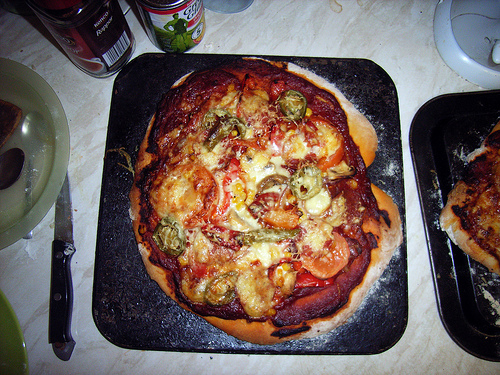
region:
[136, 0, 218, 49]
A can of vegetables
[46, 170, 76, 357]
A knife with the tip hidden under a plate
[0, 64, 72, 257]
A green plate with food on it, and a spoon underneath it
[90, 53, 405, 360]
A pizza on a platter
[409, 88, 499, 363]
Part of a platter of pizza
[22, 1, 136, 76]
A bottle of juice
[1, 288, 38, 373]
The edge of a green plate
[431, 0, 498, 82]
A white and grey object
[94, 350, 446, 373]
A white marble table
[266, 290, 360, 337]
Burnt sauce and crust of the pizza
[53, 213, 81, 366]
Knife to the left of the plate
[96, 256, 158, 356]
Bottom left corner of the black pate the pizza rests on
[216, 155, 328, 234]
Cheesy middle of the pizza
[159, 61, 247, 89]
Crispy crust at the top of the pizza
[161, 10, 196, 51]
Green giant on the can of vegetables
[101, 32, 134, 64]
UPC code on the can on the left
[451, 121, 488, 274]
What can be seen of the pizza on the right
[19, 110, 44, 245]
Spoon underneath the transparent plate on the left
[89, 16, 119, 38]
White writing on the can on the left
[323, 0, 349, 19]
Small dirty spot on the tablecloth at the top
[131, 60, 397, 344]
the pizza has many toppings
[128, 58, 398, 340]
the pizza looks burned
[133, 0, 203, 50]
a can of green beans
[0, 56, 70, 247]
the plate is green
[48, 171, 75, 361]
the knife has a black handle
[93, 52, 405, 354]
the plan is black and square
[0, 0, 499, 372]
the table is made of marble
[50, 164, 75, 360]
the knife is dirty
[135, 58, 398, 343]
the pizza has jalepeno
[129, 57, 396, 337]
the pizza has sauce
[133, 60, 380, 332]
Gourmet focaccia served at a restaurant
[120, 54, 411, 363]
Focaccia served on caste iron slab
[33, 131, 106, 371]
Cutting knife for focaccia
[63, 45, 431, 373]
White marble table top in the background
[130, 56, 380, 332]
Focaccia has cheese, tomatoes, and green peppers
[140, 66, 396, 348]
Focaccia has a well toasted crust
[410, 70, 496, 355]
Edge of second serving of focaccia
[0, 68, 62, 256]
Beige plate and silver spoon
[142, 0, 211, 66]
Can of Green Giant bean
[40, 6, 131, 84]
Bottle of red ground pepper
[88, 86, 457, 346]
The pizza is on a pan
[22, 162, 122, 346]
There is a knife next to the pan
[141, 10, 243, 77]
The can has the green giant on it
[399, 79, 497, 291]
There is another pizza to the side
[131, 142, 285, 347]
The pizza has a green vegetable on it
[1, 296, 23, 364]
This dish is green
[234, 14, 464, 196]
The pizza is on the counter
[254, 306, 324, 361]
The pizza crust is a little bit burned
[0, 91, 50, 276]
There is a spoon on this dish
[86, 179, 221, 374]
The pan is dark silver